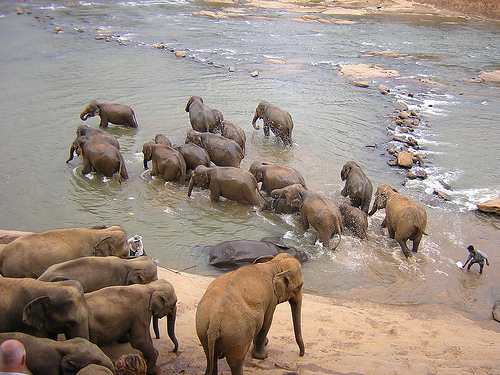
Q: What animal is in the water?
A: Elephants.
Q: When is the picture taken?
A: Daytime.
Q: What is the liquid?
A: Water.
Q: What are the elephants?
A: Animals.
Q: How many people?
A: Two.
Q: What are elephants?
A: Mammals.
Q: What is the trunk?
A: A nose.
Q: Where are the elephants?
A: Crossing the river.